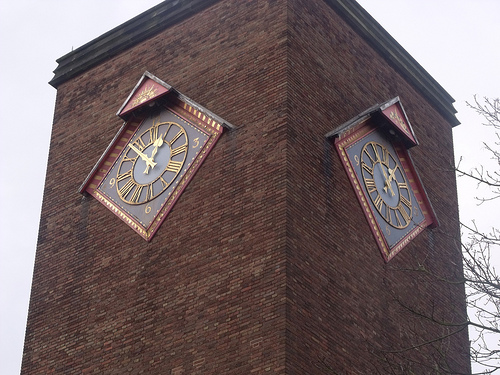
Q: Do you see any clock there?
A: Yes, there is a clock.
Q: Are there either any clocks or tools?
A: Yes, there is a clock.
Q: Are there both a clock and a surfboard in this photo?
A: No, there is a clock but no surfboards.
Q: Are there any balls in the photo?
A: No, there are no balls.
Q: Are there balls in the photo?
A: No, there are no balls.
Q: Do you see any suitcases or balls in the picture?
A: No, there are no balls or suitcases.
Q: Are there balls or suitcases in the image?
A: No, there are no balls or suitcases.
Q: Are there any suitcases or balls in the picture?
A: No, there are no balls or suitcases.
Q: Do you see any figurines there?
A: No, there are no figurines.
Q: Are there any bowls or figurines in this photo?
A: No, there are no figurines or bowls.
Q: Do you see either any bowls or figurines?
A: No, there are no figurines or bowls.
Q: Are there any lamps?
A: No, there are no lamps.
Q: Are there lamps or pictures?
A: No, there are no lamps or pictures.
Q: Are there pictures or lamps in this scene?
A: No, there are no lamps or pictures.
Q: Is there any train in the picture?
A: No, there are no trains.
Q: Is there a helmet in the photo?
A: No, there are no helmets.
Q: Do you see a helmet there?
A: No, there are no helmets.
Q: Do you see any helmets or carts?
A: No, there are no helmets or carts.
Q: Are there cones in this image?
A: No, there are no cones.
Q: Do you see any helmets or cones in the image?
A: No, there are no cones or helmets.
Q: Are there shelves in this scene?
A: No, there are no shelves.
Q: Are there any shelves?
A: No, there are no shelves.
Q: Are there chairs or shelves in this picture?
A: No, there are no shelves or chairs.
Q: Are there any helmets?
A: No, there are no helmets.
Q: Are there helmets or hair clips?
A: No, there are no helmets or hair clips.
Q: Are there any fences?
A: No, there are no fences.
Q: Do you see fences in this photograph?
A: No, there are no fences.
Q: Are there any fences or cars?
A: No, there are no fences or cars.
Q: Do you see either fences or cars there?
A: No, there are no fences or cars.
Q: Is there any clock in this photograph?
A: Yes, there is a clock.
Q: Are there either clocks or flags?
A: Yes, there is a clock.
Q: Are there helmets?
A: No, there are no helmets.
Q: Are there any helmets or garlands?
A: No, there are no helmets or garlands.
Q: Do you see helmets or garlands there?
A: No, there are no helmets or garlands.